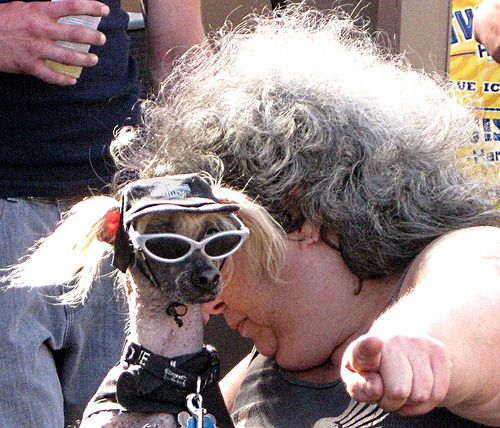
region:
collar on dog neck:
[123, 350, 228, 379]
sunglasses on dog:
[132, 228, 256, 262]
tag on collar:
[177, 387, 218, 427]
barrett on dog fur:
[98, 210, 126, 243]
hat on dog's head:
[126, 171, 235, 218]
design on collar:
[162, 367, 193, 384]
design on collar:
[124, 343, 149, 363]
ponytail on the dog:
[3, 188, 118, 302]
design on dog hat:
[138, 180, 196, 197]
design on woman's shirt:
[293, 396, 396, 426]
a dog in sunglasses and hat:
[76, 176, 316, 329]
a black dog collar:
[124, 333, 232, 405]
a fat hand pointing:
[330, 313, 467, 413]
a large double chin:
[235, 298, 310, 369]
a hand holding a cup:
[4, 10, 134, 86]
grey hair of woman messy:
[158, 18, 462, 209]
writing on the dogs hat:
[136, 178, 193, 200]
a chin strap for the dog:
[154, 288, 191, 333]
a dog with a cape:
[93, 335, 241, 425]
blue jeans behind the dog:
[2, 195, 126, 422]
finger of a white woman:
[342, 336, 384, 366]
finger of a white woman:
[376, 347, 411, 410]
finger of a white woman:
[406, 354, 428, 410]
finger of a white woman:
[403, 358, 446, 420]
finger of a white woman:
[343, 374, 383, 399]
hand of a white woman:
[341, 332, 452, 418]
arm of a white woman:
[385, 228, 497, 408]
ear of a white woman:
[282, 183, 327, 246]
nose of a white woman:
[205, 296, 230, 316]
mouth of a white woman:
[226, 315, 250, 339]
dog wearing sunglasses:
[121, 201, 261, 277]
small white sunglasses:
[130, 214, 259, 278]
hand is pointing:
[333, 322, 463, 406]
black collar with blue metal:
[130, 345, 223, 422]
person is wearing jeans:
[2, 176, 144, 398]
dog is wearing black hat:
[120, 165, 260, 255]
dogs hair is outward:
[28, 178, 131, 305]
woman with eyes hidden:
[187, 143, 410, 360]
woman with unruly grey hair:
[175, 37, 471, 239]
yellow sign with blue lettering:
[433, 3, 495, 164]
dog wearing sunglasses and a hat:
[120, 178, 245, 295]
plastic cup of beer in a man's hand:
[42, 2, 100, 84]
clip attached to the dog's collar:
[182, 393, 211, 426]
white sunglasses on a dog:
[128, 223, 244, 264]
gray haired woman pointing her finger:
[138, 30, 488, 403]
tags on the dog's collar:
[173, 405, 219, 425]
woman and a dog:
[77, 18, 466, 413]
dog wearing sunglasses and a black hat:
[25, 182, 283, 303]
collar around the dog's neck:
[115, 343, 225, 393]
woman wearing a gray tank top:
[115, 37, 496, 417]